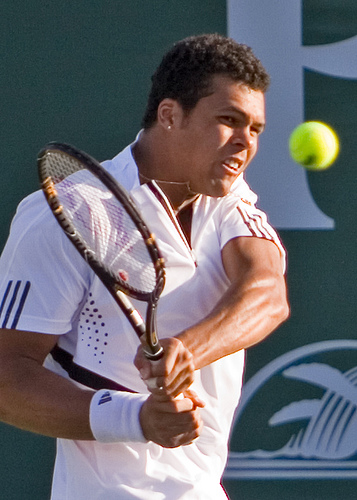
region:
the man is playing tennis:
[11, 40, 352, 489]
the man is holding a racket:
[15, 143, 238, 446]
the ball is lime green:
[281, 100, 343, 184]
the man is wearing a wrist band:
[63, 368, 159, 459]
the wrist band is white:
[63, 373, 154, 459]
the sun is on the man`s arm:
[148, 237, 310, 433]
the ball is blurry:
[261, 116, 350, 218]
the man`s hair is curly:
[129, 31, 276, 123]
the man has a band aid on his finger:
[120, 367, 168, 393]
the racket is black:
[17, 107, 197, 358]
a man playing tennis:
[0, 33, 289, 498]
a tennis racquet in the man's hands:
[33, 138, 166, 368]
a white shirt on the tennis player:
[0, 125, 285, 498]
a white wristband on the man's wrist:
[87, 386, 150, 441]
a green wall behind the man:
[0, 0, 354, 498]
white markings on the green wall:
[222, 19, 355, 497]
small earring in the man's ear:
[165, 124, 171, 130]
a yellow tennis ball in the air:
[287, 118, 340, 170]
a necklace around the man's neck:
[140, 168, 199, 195]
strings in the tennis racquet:
[43, 148, 160, 294]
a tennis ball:
[287, 120, 340, 171]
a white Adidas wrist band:
[87, 385, 147, 444]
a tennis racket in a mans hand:
[38, 140, 167, 361]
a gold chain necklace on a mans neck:
[139, 171, 197, 199]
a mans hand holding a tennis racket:
[133, 338, 195, 397]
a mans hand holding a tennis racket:
[140, 391, 203, 450]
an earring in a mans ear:
[167, 125, 170, 128]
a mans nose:
[233, 126, 253, 148]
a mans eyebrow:
[219, 102, 248, 116]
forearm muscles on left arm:
[179, 284, 291, 370]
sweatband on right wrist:
[85, 387, 152, 447]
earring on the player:
[161, 119, 177, 136]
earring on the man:
[161, 121, 173, 139]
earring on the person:
[161, 119, 177, 135]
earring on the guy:
[153, 116, 180, 145]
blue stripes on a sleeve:
[0, 268, 32, 340]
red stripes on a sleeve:
[237, 203, 274, 246]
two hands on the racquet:
[126, 332, 204, 463]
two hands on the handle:
[131, 331, 203, 463]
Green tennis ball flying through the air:
[275, 111, 354, 181]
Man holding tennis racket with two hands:
[41, 55, 276, 461]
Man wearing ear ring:
[145, 88, 263, 178]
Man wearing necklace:
[124, 51, 265, 210]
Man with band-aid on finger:
[136, 365, 189, 395]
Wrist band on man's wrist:
[49, 354, 184, 478]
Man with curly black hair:
[145, 31, 279, 186]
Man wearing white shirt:
[39, 160, 287, 319]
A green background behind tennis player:
[18, 17, 128, 124]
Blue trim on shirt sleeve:
[4, 215, 37, 351]